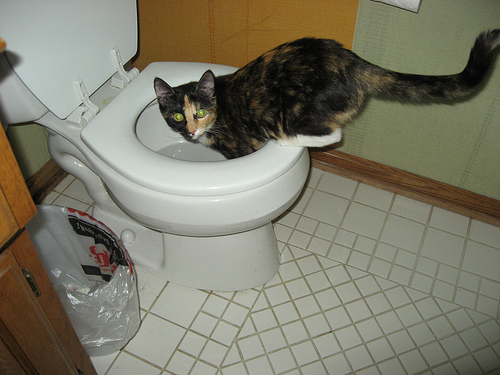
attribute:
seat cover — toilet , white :
[1, 1, 140, 120]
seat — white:
[81, 61, 306, 196]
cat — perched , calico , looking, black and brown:
[138, 33, 496, 154]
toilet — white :
[0, 4, 312, 290]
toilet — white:
[62, 41, 392, 333]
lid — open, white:
[0, 1, 142, 119]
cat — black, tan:
[152, 26, 499, 159]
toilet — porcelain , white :
[5, 8, 343, 288]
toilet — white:
[151, 57, 315, 285]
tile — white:
[322, 299, 353, 330]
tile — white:
[352, 273, 379, 294]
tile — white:
[419, 339, 446, 364]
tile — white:
[249, 307, 277, 332]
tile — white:
[297, 251, 325, 273]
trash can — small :
[32, 199, 147, 357]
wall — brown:
[126, 0, 358, 67]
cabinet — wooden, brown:
[1, 272, 57, 334]